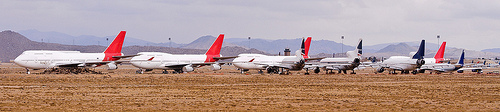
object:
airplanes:
[128, 33, 241, 74]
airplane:
[10, 30, 142, 74]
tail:
[409, 39, 427, 69]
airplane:
[373, 39, 425, 75]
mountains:
[0, 29, 497, 63]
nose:
[12, 50, 28, 67]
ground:
[2, 71, 498, 112]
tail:
[412, 39, 426, 58]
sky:
[0, 0, 498, 52]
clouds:
[0, 6, 499, 30]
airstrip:
[0, 74, 499, 89]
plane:
[228, 37, 326, 76]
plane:
[320, 38, 367, 74]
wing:
[114, 54, 143, 58]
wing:
[350, 38, 361, 63]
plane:
[417, 41, 460, 75]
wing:
[435, 40, 449, 63]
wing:
[454, 49, 467, 69]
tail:
[101, 30, 127, 53]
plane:
[126, 32, 239, 74]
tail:
[203, 33, 226, 63]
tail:
[298, 36, 311, 61]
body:
[231, 36, 326, 75]